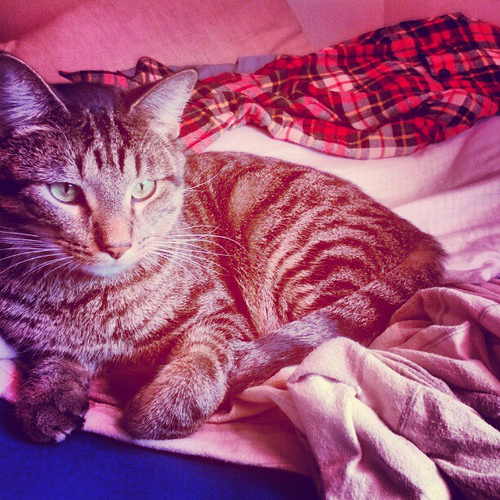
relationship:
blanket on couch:
[59, 12, 499, 160] [1, 1, 500, 500]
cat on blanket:
[0, 50, 451, 445] [0, 286, 499, 499]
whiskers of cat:
[0, 224, 250, 295] [0, 50, 451, 445]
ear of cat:
[124, 66, 197, 141] [0, 50, 451, 445]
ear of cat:
[0, 51, 71, 131] [0, 50, 451, 445]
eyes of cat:
[48, 178, 158, 208] [0, 50, 451, 445]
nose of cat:
[103, 244, 130, 260] [0, 50, 451, 445]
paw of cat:
[13, 379, 91, 445] [0, 50, 451, 445]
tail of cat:
[229, 246, 446, 396] [0, 50, 451, 445]